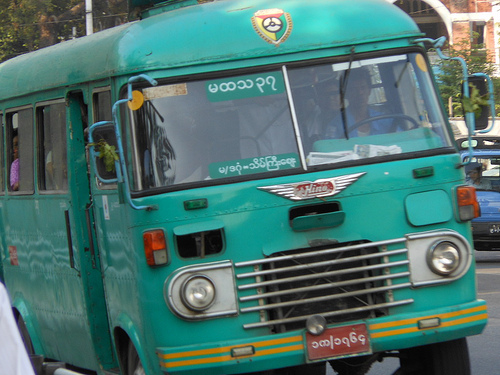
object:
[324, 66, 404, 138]
driver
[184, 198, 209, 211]
light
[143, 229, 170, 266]
blinker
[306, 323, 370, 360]
license plate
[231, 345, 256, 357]
light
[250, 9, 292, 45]
logo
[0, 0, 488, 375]
automobile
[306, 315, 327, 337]
light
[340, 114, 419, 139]
steering wheel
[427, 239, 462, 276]
headlight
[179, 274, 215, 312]
headlight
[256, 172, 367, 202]
emblem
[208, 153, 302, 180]
sticker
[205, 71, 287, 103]
sticker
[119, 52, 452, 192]
windshield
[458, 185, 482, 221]
light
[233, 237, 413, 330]
grill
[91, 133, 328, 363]
section